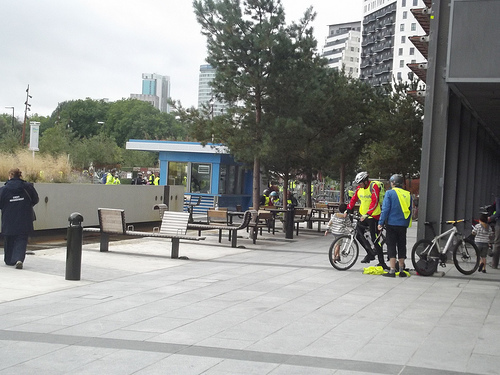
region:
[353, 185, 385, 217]
man wearing a yellow safety vest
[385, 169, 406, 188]
man wearing a black hat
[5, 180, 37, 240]
woman wearing a black jacket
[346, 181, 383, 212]
man wearing a red shirt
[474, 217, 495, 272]
Child wearing gray pants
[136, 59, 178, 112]
skyscraper in the distance view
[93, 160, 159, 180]
group of people standing next to a wall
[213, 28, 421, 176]
Leaves on top of trees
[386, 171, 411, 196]
man with gray hair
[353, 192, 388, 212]
The man is wearing a yellow vest.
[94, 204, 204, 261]
Benches on the walkway.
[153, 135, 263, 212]
A blue booth by the benches.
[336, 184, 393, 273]
A man on the bicycle.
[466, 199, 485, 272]
A little boy walking pass the bike.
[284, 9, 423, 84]
Buildings in the background.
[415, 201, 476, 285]
Bike parked by the pole.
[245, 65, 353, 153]
The trees are green.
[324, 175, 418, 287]
people standing by bikes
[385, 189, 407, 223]
yellow jersey on person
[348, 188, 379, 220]
yellow jersey on person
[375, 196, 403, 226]
blue jacket on person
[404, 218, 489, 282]
bike parked on walk way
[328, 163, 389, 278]
person walking with bike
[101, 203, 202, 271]
wooden benches on ground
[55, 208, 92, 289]
short black metal pole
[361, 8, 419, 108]
large white building in back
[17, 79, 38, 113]
tall telephone poles in back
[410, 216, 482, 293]
one white bicycle on light pavement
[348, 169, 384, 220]
one man wearing bright yellow vest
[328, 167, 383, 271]
bicyclist wearing long sleeved red jacket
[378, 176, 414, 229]
person wearing long sleeved blue jacket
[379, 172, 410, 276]
person wearing dark capri pants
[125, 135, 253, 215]
little blue building with windows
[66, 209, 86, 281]
one dark metal pole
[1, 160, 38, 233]
one person wearing dark jacket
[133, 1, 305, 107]
pine tree against gray sky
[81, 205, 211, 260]
bench with two backrest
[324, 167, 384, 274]
man rides a bike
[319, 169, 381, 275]
man wears a helmet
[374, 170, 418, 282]
woman wears blue top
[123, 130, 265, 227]
a cabin color blue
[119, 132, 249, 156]
roof white and blue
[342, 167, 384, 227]
man has a yellow vest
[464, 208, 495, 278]
girl has behind a bike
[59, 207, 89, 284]
the pole is black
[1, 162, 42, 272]
woman wears is blue